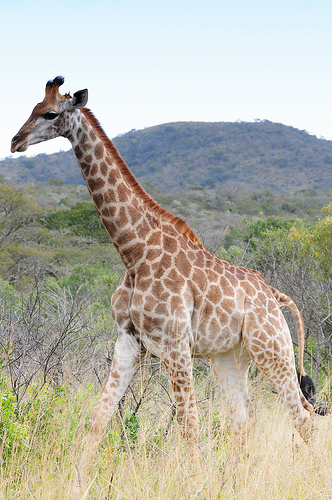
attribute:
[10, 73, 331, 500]
giraffe — adult, walking, facing left, white, brown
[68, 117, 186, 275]
neck — long, spotted, brown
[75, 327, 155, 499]
leg — long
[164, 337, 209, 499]
leg — long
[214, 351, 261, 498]
leg — long, hind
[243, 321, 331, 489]
leg — long, hind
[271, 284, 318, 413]
tail — long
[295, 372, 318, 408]
hair — black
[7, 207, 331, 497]
ground — green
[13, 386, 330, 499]
grass — long, dry, tall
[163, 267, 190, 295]
spot — brown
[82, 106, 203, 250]
mane — brown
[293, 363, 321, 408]
tuft — hairy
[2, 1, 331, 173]
sky — blue, clear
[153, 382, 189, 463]
branch — bare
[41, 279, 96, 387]
branch — bare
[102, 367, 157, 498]
branch — bare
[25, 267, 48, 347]
branch — bare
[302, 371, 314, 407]
tip — black